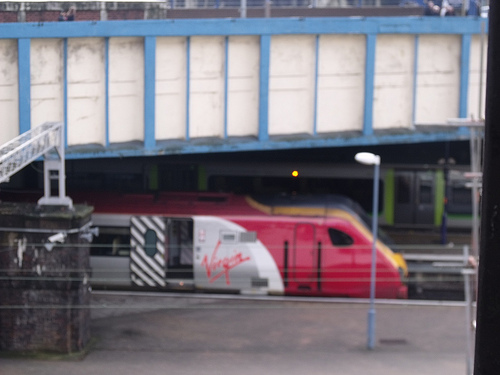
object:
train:
[0, 214, 410, 297]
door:
[164, 217, 196, 290]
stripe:
[282, 220, 321, 295]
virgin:
[198, 240, 252, 287]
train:
[16, 162, 482, 231]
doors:
[393, 165, 435, 228]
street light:
[354, 151, 381, 351]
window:
[142, 229, 158, 257]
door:
[129, 210, 166, 289]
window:
[327, 226, 355, 248]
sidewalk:
[0, 290, 475, 374]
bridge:
[0, 7, 490, 160]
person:
[57, 4, 75, 21]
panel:
[68, 39, 105, 145]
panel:
[109, 37, 143, 147]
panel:
[155, 37, 186, 139]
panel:
[190, 37, 225, 138]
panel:
[266, 36, 314, 136]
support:
[144, 33, 155, 147]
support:
[257, 33, 269, 141]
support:
[362, 35, 375, 137]